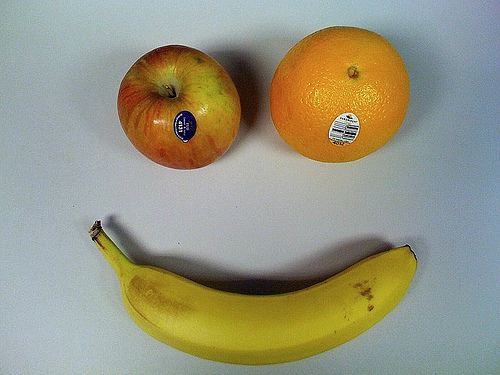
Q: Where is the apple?
A: Next to the orange.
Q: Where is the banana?
A: Under the orange.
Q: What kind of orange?
A: Navel.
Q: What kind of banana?
A: Ripe.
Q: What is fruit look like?
A: Smiley face.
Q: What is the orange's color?
A: Orange.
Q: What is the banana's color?
A: Yellow.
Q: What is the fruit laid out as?
A: In the form of a face.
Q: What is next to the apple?
A: An orange.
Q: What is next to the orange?
A: An apple.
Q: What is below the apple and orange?
A: A banana.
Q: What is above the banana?
A: An apple and orange.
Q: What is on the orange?
A: A label.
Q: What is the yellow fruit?
A: A banana.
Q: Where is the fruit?
A: On the table.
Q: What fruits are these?
A: An apple, orange, and banana.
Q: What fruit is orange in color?
A: The orange.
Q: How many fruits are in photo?
A: Three.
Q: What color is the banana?
A: Yellow.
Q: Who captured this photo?
A: A photographer.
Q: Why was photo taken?
A: Show a fruit smile.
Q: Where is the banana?
A: On the bottom.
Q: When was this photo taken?
A: In the daytime.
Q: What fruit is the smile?
A: The banana.